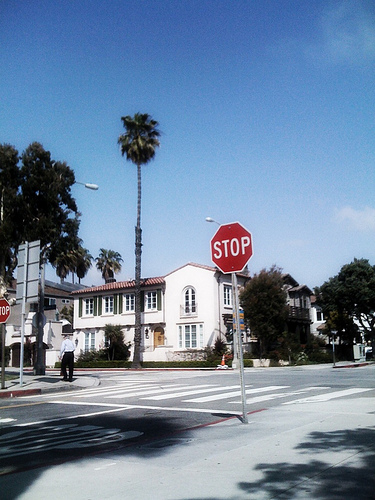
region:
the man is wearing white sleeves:
[51, 325, 126, 400]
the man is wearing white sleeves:
[49, 319, 88, 366]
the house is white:
[102, 243, 297, 384]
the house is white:
[118, 232, 224, 332]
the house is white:
[117, 278, 314, 443]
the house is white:
[160, 253, 239, 383]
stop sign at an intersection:
[204, 220, 267, 438]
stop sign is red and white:
[203, 201, 268, 281]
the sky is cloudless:
[155, 99, 368, 227]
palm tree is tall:
[106, 113, 166, 361]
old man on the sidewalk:
[57, 333, 79, 376]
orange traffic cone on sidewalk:
[216, 351, 228, 368]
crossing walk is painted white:
[93, 379, 295, 409]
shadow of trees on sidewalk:
[258, 415, 370, 494]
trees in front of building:
[248, 263, 369, 358]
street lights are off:
[46, 166, 101, 327]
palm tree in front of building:
[107, 107, 170, 365]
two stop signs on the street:
[2, 216, 270, 324]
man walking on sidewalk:
[55, 338, 83, 392]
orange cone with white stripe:
[215, 354, 238, 380]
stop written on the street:
[5, 422, 159, 460]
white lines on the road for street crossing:
[93, 375, 329, 413]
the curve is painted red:
[94, 365, 214, 375]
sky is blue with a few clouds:
[180, 73, 349, 142]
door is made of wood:
[154, 329, 169, 357]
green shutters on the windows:
[71, 292, 168, 322]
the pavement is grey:
[220, 451, 225, 460]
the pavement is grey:
[197, 469, 199, 479]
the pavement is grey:
[196, 460, 201, 462]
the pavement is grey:
[222, 439, 232, 451]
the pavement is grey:
[182, 469, 192, 475]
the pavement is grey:
[240, 430, 243, 433]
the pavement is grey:
[165, 478, 174, 481]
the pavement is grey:
[199, 470, 205, 485]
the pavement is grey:
[197, 465, 206, 473]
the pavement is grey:
[214, 458, 219, 468]